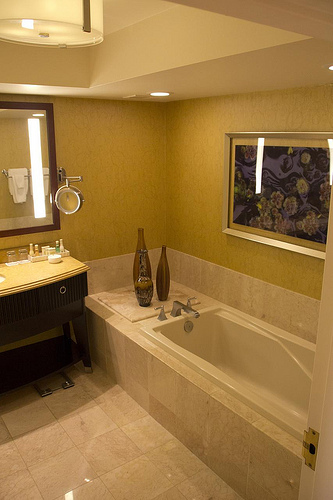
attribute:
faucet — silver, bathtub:
[170, 299, 199, 319]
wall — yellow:
[99, 112, 209, 210]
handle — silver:
[57, 286, 70, 294]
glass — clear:
[5, 248, 18, 267]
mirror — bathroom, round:
[54, 186, 83, 215]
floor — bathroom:
[1, 360, 244, 497]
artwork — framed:
[230, 140, 327, 248]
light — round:
[151, 89, 167, 102]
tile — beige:
[56, 404, 117, 446]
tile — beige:
[76, 426, 144, 475]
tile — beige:
[146, 437, 207, 484]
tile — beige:
[99, 391, 149, 427]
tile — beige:
[27, 446, 97, 497]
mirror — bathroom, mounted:
[52, 169, 84, 214]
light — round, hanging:
[0, 0, 103, 48]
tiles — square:
[7, 367, 244, 497]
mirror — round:
[51, 167, 83, 215]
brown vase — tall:
[135, 247, 152, 308]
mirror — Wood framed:
[0, 96, 63, 238]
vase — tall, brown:
[126, 229, 153, 307]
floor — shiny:
[43, 399, 165, 483]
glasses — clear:
[5, 247, 29, 263]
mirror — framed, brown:
[1, 104, 56, 234]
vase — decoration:
[133, 225, 151, 286]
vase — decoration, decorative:
[135, 246, 153, 305]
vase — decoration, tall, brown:
[154, 243, 170, 299]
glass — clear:
[16, 248, 28, 261]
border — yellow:
[228, 137, 329, 250]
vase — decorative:
[132, 227, 151, 282]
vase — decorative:
[156, 244, 169, 300]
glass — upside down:
[5, 249, 17, 261]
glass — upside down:
[16, 247, 27, 260]